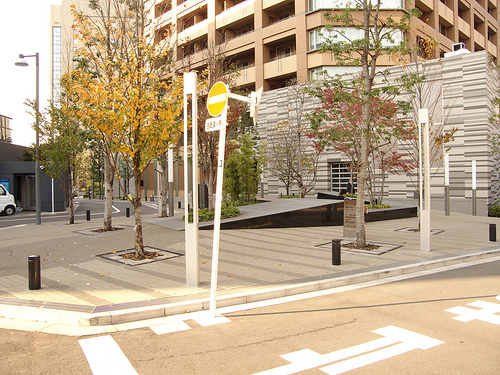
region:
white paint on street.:
[384, 323, 429, 358]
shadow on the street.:
[479, 260, 496, 279]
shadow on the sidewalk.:
[72, 263, 104, 278]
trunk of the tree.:
[354, 200, 366, 242]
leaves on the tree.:
[105, 93, 126, 108]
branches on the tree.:
[431, 85, 441, 113]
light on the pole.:
[13, 45, 34, 68]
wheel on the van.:
[5, 204, 14, 215]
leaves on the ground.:
[57, 262, 84, 284]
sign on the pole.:
[207, 87, 232, 112]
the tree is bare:
[273, 141, 300, 181]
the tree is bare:
[401, 84, 447, 115]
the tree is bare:
[268, 133, 287, 166]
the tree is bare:
[288, 136, 323, 195]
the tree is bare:
[413, 99, 464, 133]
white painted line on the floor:
[74, 323, 115, 370]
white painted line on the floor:
[314, 307, 398, 370]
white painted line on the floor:
[418, 289, 488, 341]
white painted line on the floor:
[161, 300, 233, 331]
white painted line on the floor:
[266, 286, 312, 316]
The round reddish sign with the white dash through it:
[208, 80, 228, 115]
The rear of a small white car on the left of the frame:
[3, 180, 18, 215]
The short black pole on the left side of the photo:
[28, 255, 44, 290]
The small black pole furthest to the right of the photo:
[485, 220, 499, 242]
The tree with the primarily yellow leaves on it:
[74, 55, 185, 267]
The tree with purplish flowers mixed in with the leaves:
[309, 72, 424, 207]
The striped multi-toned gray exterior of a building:
[259, 55, 494, 196]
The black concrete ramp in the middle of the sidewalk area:
[166, 201, 346, 227]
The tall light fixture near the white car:
[10, 58, 46, 223]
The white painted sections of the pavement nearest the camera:
[69, 295, 497, 372]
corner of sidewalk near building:
[2, 195, 496, 326]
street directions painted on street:
[192, 296, 498, 373]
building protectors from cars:
[26, 252, 43, 292]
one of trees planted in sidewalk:
[58, 4, 181, 266]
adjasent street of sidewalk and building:
[1, 196, 151, 213]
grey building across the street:
[1, 143, 70, 211]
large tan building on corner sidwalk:
[137, 2, 495, 207]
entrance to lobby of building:
[329, 159, 366, 196]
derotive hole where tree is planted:
[92, 245, 182, 269]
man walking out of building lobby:
[347, 176, 354, 191]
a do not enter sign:
[204, 74, 247, 125]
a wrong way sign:
[199, 83, 251, 142]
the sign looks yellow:
[196, 68, 249, 136]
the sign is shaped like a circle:
[197, 75, 267, 149]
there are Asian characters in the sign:
[188, 115, 249, 132]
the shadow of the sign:
[213, 287, 498, 320]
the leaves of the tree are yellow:
[50, 8, 190, 268]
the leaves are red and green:
[312, 71, 448, 193]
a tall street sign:
[204, 70, 259, 319]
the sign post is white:
[196, 82, 267, 333]